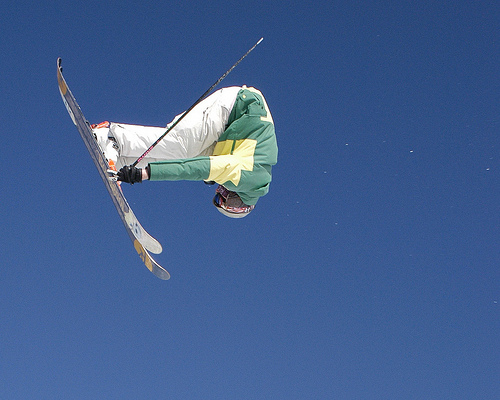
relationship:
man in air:
[92, 86, 279, 220] [1, 1, 498, 400]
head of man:
[212, 186, 256, 219] [92, 86, 279, 220]